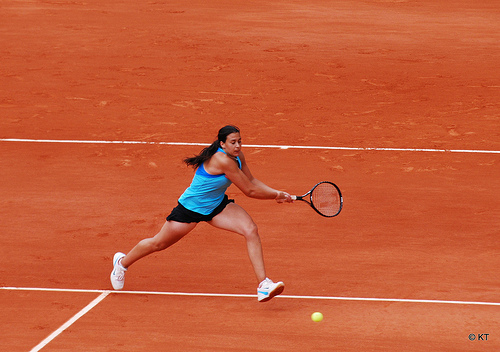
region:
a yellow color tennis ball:
[307, 305, 329, 329]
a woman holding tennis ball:
[274, 172, 351, 226]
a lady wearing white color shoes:
[108, 253, 291, 308]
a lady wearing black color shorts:
[163, 194, 238, 225]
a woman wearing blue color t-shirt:
[174, 155, 232, 216]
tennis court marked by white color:
[16, 275, 466, 310]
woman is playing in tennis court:
[40, 25, 455, 310]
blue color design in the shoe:
[256, 288, 271, 295]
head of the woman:
[213, 119, 250, 156]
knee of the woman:
[241, 213, 263, 250]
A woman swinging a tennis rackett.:
[108, 124, 343, 301]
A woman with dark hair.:
[109, 124, 293, 301]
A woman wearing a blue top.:
[109, 125, 292, 302]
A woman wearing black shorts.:
[108, 124, 293, 301]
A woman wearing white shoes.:
[110, 124, 293, 302]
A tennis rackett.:
[291, 181, 344, 217]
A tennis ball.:
[309, 309, 324, 322]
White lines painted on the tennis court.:
[1, 136, 498, 350]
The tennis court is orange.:
[2, 1, 497, 122]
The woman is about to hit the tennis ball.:
[108, 123, 344, 301]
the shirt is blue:
[186, 129, 256, 226]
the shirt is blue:
[151, 145, 243, 241]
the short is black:
[131, 172, 249, 224]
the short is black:
[138, 190, 262, 247]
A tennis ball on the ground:
[310, 302, 325, 329]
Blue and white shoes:
[241, 272, 297, 309]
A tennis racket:
[286, 168, 355, 224]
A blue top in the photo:
[175, 156, 240, 209]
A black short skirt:
[147, 194, 247, 226]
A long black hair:
[176, 102, 238, 173]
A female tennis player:
[96, 121, 289, 313]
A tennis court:
[369, 147, 445, 244]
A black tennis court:
[296, 174, 348, 226]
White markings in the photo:
[340, 136, 465, 162]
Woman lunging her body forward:
[107, 120, 291, 302]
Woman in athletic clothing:
[108, 124, 292, 304]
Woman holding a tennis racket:
[104, 121, 344, 301]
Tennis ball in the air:
[302, 308, 328, 325]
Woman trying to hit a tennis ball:
[100, 121, 344, 326]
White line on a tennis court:
[0, 135, 499, 157]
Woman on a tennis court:
[104, 115, 344, 326]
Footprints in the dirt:
[11, 20, 493, 187]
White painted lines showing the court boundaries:
[2, 272, 497, 350]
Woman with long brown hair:
[105, 120, 291, 305]